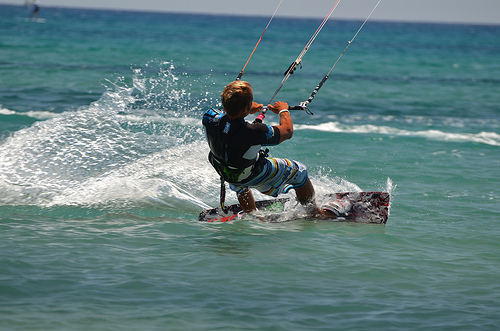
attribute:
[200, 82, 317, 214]
boarder — leaning, boarding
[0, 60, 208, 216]
spray — flying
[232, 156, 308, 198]
shorts — striped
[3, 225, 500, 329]
ocean — dark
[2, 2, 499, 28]
sky — blue, gray, cloudy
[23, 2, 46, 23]
surfer — blurry, real